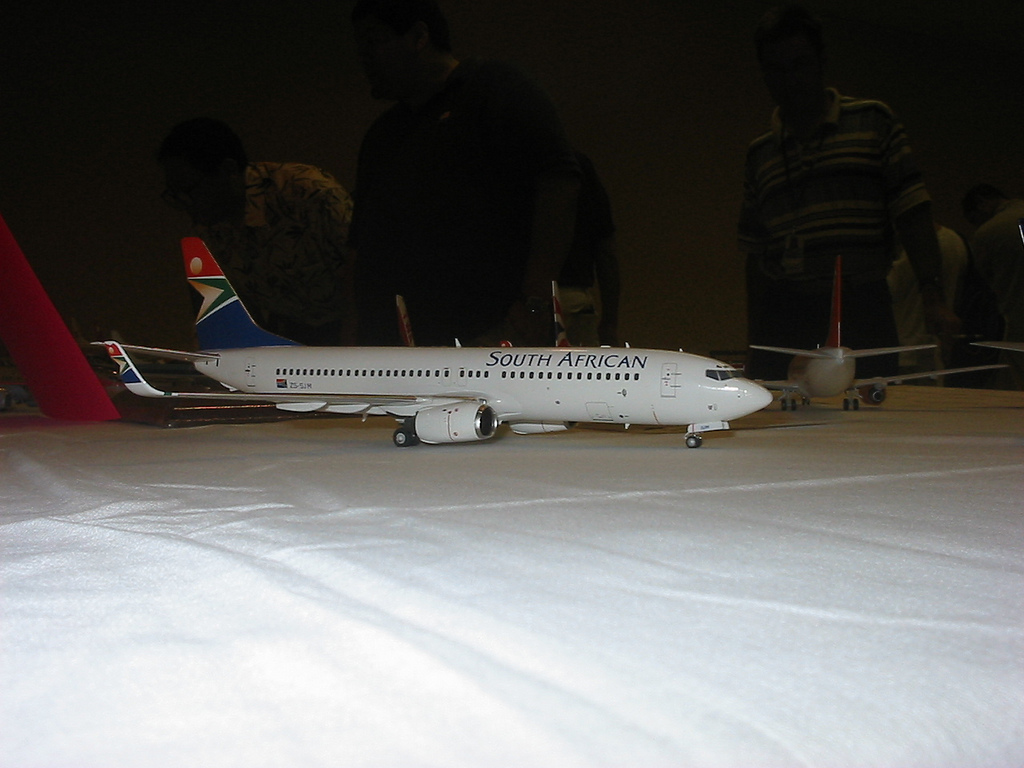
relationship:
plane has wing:
[89, 215, 903, 458] [90, 344, 369, 448]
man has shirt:
[716, 37, 980, 337] [729, 96, 922, 286]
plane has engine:
[89, 215, 903, 458] [387, 399, 504, 460]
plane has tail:
[89, 215, 903, 458] [148, 202, 296, 356]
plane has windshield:
[89, 215, 903, 458] [679, 349, 776, 395]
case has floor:
[15, 12, 829, 765] [243, 438, 992, 754]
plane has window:
[89, 215, 903, 458] [563, 366, 650, 391]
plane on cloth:
[89, 215, 903, 458] [65, 520, 396, 657]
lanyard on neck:
[753, 128, 818, 189] [757, 79, 877, 149]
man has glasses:
[716, 37, 980, 337] [757, 43, 827, 81]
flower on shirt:
[245, 219, 332, 274] [215, 155, 390, 328]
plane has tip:
[89, 215, 903, 458] [167, 225, 224, 278]